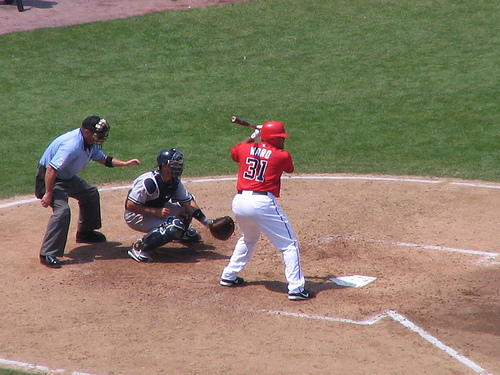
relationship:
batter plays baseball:
[219, 121, 312, 300] [18, 81, 388, 334]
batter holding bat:
[219, 121, 312, 300] [224, 109, 259, 138]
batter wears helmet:
[219, 121, 312, 300] [255, 118, 290, 140]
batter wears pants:
[219, 121, 312, 300] [219, 190, 307, 292]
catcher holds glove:
[124, 147, 234, 262] [210, 215, 235, 240]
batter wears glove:
[219, 121, 312, 300] [250, 123, 262, 138]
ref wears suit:
[35, 115, 140, 268] [32, 126, 110, 274]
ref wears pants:
[35, 115, 140, 268] [32, 166, 106, 256]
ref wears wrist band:
[35, 115, 140, 268] [103, 152, 117, 173]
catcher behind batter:
[119, 147, 238, 265] [228, 103, 320, 303]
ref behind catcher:
[35, 115, 140, 268] [123, 147, 211, 261]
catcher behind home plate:
[124, 147, 234, 262] [328, 269, 380, 289]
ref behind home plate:
[27, 112, 143, 267] [328, 269, 380, 289]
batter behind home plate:
[219, 121, 312, 300] [328, 269, 380, 289]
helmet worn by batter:
[248, 125, 294, 150] [219, 119, 316, 304]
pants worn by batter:
[221, 190, 306, 294] [219, 121, 312, 300]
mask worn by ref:
[90, 120, 112, 145] [35, 115, 140, 268]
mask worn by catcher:
[168, 148, 187, 187] [130, 139, 206, 269]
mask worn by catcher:
[169, 151, 184, 186] [112, 147, 200, 261]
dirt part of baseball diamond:
[1, 172, 498, 372] [0, 151, 498, 372]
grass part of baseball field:
[1, 2, 498, 212] [3, 2, 498, 374]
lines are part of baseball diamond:
[349, 305, 457, 370] [318, 244, 386, 301]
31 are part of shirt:
[243, 157, 267, 183] [227, 139, 293, 196]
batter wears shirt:
[219, 119, 316, 304] [227, 139, 293, 196]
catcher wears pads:
[124, 147, 234, 262] [146, 176, 175, 201]